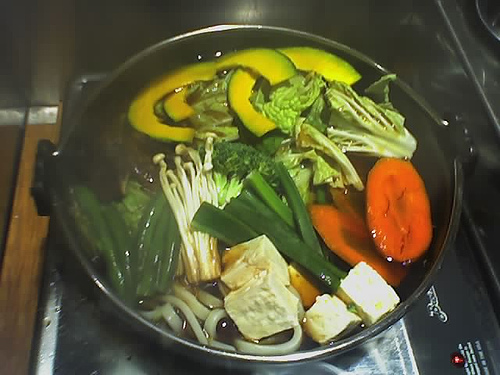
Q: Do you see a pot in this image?
A: Yes, there is a pot.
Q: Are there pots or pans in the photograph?
A: Yes, there is a pot.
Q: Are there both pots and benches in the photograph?
A: No, there is a pot but no benches.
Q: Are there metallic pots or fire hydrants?
A: Yes, there is a metal pot.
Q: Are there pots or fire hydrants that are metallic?
A: Yes, the pot is metallic.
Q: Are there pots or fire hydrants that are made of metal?
A: Yes, the pot is made of metal.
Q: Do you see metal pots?
A: Yes, there is a pot that is made of metal.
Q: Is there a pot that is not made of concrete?
A: Yes, there is a pot that is made of metal.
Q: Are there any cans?
A: No, there are no cans.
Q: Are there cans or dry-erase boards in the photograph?
A: No, there are no cans or dry-erase boards.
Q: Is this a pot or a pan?
A: This is a pot.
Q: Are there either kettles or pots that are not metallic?
A: No, there is a pot but it is metallic.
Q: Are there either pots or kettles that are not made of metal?
A: No, there is a pot but it is made of metal.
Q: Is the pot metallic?
A: Yes, the pot is metallic.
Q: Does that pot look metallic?
A: Yes, the pot is metallic.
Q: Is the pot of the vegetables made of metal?
A: Yes, the pot is made of metal.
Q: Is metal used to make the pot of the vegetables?
A: Yes, the pot is made of metal.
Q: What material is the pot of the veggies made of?
A: The pot is made of metal.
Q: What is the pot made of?
A: The pot is made of metal.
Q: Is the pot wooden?
A: No, the pot is metallic.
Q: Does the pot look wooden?
A: No, the pot is metallic.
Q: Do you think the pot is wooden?
A: No, the pot is metallic.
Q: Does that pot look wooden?
A: No, the pot is metallic.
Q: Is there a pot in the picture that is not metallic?
A: No, there is a pot but it is metallic.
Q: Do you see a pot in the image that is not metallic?
A: No, there is a pot but it is metallic.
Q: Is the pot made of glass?
A: No, the pot is made of metal.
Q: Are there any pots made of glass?
A: No, there is a pot but it is made of metal.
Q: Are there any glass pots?
A: No, there is a pot but it is made of metal.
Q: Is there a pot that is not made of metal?
A: No, there is a pot but it is made of metal.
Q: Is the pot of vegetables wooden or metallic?
A: The pot is metallic.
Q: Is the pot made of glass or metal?
A: The pot is made of metal.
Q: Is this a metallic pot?
A: Yes, this is a metallic pot.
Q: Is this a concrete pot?
A: No, this is a metallic pot.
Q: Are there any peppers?
A: Yes, there are peppers.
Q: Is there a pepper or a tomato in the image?
A: Yes, there are peppers.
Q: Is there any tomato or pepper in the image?
A: Yes, there are peppers.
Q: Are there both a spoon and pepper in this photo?
A: No, there are peppers but no spoons.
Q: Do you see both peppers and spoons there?
A: No, there are peppers but no spoons.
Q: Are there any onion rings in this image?
A: No, there are no onion rings.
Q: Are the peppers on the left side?
A: Yes, the peppers are on the left of the image.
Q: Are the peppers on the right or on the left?
A: The peppers are on the left of the image.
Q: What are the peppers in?
A: The peppers are in the pot.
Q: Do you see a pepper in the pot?
A: Yes, there are peppers in the pot.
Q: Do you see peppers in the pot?
A: Yes, there are peppers in the pot.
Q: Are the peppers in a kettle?
A: No, the peppers are in the pot.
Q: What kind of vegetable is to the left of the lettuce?
A: The vegetables are peppers.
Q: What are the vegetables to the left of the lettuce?
A: The vegetables are peppers.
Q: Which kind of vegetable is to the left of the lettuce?
A: The vegetables are peppers.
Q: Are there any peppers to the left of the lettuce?
A: Yes, there are peppers to the left of the lettuce.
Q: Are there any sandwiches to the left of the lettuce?
A: No, there are peppers to the left of the lettuce.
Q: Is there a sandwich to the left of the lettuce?
A: No, there are peppers to the left of the lettuce.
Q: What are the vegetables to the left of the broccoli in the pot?
A: The vegetables are peppers.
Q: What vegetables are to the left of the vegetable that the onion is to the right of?
A: The vegetables are peppers.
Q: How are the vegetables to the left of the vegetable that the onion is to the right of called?
A: The vegetables are peppers.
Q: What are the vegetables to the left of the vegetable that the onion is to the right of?
A: The vegetables are peppers.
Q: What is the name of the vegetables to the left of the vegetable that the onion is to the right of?
A: The vegetables are peppers.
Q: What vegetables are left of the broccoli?
A: The vegetables are peppers.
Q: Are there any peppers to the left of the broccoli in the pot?
A: Yes, there are peppers to the left of the broccoli.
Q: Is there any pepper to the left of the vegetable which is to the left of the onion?
A: Yes, there are peppers to the left of the broccoli.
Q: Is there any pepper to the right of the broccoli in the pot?
A: No, the peppers are to the left of the broccoli.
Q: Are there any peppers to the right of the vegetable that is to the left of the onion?
A: No, the peppers are to the left of the broccoli.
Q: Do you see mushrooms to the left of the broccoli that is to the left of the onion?
A: No, there are peppers to the left of the broccoli.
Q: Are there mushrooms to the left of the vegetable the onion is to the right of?
A: No, there are peppers to the left of the broccoli.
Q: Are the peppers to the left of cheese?
A: No, the peppers are to the left of the broccoli.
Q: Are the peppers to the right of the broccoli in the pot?
A: No, the peppers are to the left of the broccoli.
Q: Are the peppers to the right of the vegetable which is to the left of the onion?
A: No, the peppers are to the left of the broccoli.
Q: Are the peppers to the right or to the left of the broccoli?
A: The peppers are to the left of the broccoli.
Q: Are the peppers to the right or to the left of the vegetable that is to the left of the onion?
A: The peppers are to the left of the broccoli.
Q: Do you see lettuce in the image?
A: Yes, there is lettuce.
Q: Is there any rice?
A: No, there is no rice.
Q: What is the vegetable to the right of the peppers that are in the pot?
A: The vegetable is lettuce.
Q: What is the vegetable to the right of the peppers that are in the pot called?
A: The vegetable is lettuce.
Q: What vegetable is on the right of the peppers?
A: The vegetable is lettuce.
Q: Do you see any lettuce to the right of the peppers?
A: Yes, there is lettuce to the right of the peppers.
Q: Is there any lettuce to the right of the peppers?
A: Yes, there is lettuce to the right of the peppers.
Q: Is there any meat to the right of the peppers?
A: No, there is lettuce to the right of the peppers.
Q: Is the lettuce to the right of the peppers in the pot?
A: Yes, the lettuce is to the right of the peppers.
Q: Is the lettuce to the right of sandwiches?
A: No, the lettuce is to the right of the peppers.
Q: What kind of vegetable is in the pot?
A: The vegetable is lettuce.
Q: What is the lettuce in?
A: The lettuce is in the pot.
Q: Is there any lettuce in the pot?
A: Yes, there is lettuce in the pot.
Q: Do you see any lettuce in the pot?
A: Yes, there is lettuce in the pot.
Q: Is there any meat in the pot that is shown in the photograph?
A: No, there is lettuce in the pot.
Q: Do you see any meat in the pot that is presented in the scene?
A: No, there is lettuce in the pot.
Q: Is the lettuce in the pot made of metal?
A: Yes, the lettuce is in the pot.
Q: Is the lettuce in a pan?
A: No, the lettuce is in the pot.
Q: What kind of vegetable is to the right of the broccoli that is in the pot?
A: The vegetable is lettuce.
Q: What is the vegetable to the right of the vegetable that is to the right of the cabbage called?
A: The vegetable is lettuce.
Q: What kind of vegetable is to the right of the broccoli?
A: The vegetable is lettuce.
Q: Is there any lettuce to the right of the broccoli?
A: Yes, there is lettuce to the right of the broccoli.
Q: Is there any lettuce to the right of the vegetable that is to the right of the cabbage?
A: Yes, there is lettuce to the right of the broccoli.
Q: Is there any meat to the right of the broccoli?
A: No, there is lettuce to the right of the broccoli.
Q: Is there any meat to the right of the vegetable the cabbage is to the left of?
A: No, there is lettuce to the right of the broccoli.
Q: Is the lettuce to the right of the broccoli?
A: Yes, the lettuce is to the right of the broccoli.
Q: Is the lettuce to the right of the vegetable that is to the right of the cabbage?
A: Yes, the lettuce is to the right of the broccoli.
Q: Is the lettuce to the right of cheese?
A: No, the lettuce is to the right of the broccoli.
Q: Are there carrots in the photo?
A: Yes, there is a carrot.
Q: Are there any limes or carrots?
A: Yes, there is a carrot.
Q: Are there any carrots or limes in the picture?
A: Yes, there is a carrot.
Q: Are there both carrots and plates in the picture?
A: No, there is a carrot but no plates.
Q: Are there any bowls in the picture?
A: No, there are no bowls.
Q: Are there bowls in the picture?
A: No, there are no bowls.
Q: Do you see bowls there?
A: No, there are no bowls.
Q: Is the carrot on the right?
A: Yes, the carrot is on the right of the image.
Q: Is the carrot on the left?
A: No, the carrot is on the right of the image.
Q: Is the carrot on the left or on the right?
A: The carrot is on the right of the image.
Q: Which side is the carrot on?
A: The carrot is on the right of the image.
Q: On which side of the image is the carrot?
A: The carrot is on the right of the image.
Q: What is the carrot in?
A: The carrot is in the pot.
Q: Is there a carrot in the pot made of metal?
A: Yes, there is a carrot in the pot.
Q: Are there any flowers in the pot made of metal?
A: No, there is a carrot in the pot.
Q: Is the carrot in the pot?
A: Yes, the carrot is in the pot.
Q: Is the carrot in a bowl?
A: No, the carrot is in the pot.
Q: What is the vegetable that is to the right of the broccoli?
A: The vegetable is a carrot.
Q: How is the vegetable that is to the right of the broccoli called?
A: The vegetable is a carrot.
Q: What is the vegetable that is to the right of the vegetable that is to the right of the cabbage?
A: The vegetable is a carrot.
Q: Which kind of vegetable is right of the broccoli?
A: The vegetable is a carrot.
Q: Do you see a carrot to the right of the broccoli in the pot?
A: Yes, there is a carrot to the right of the broccoli.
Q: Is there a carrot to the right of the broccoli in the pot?
A: Yes, there is a carrot to the right of the broccoli.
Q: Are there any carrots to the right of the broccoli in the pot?
A: Yes, there is a carrot to the right of the broccoli.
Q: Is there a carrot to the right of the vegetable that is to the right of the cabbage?
A: Yes, there is a carrot to the right of the broccoli.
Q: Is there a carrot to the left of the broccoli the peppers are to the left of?
A: No, the carrot is to the right of the broccoli.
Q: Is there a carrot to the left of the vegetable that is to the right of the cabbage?
A: No, the carrot is to the right of the broccoli.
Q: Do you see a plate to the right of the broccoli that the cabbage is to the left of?
A: No, there is a carrot to the right of the broccoli.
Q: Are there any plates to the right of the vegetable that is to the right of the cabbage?
A: No, there is a carrot to the right of the broccoli.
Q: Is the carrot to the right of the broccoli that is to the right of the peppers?
A: Yes, the carrot is to the right of the broccoli.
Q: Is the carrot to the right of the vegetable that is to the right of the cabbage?
A: Yes, the carrot is to the right of the broccoli.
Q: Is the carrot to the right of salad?
A: No, the carrot is to the right of the broccoli.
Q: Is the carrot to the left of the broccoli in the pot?
A: No, the carrot is to the right of the broccoli.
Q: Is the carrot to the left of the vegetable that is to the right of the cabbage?
A: No, the carrot is to the right of the broccoli.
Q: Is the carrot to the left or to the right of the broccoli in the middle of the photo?
A: The carrot is to the right of the broccoli.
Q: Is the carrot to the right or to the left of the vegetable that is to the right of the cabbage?
A: The carrot is to the right of the broccoli.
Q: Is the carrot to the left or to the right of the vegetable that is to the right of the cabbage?
A: The carrot is to the right of the broccoli.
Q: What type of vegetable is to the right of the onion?
A: The vegetable is a carrot.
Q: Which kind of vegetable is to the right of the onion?
A: The vegetable is a carrot.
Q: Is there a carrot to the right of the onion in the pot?
A: Yes, there is a carrot to the right of the onion.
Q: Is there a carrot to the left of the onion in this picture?
A: No, the carrot is to the right of the onion.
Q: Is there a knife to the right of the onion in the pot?
A: No, there is a carrot to the right of the onion.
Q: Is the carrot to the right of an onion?
A: Yes, the carrot is to the right of an onion.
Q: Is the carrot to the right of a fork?
A: No, the carrot is to the right of an onion.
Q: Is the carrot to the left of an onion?
A: No, the carrot is to the right of an onion.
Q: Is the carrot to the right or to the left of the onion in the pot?
A: The carrot is to the right of the onion.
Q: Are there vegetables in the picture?
A: Yes, there are vegetables.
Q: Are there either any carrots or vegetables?
A: Yes, there are vegetables.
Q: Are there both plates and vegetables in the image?
A: No, there are vegetables but no plates.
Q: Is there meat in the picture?
A: No, there is no meat.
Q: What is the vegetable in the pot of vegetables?
A: The vegetable is an avocado.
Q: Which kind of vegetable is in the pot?
A: The vegetable is an avocado.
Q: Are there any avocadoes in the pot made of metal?
A: Yes, there is an avocado in the pot.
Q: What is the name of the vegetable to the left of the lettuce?
A: The vegetable is an avocado.